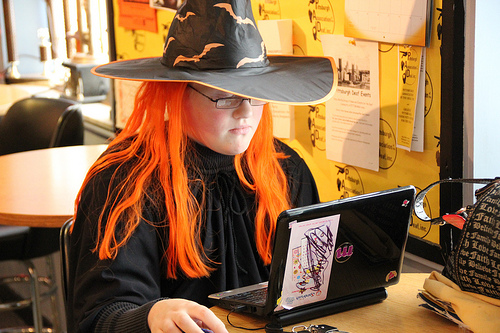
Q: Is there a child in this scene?
A: Yes, there is a child.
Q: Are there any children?
A: Yes, there is a child.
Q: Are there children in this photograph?
A: Yes, there is a child.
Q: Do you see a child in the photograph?
A: Yes, there is a child.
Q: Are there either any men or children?
A: Yes, there is a child.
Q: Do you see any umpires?
A: No, there are no umpires.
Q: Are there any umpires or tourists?
A: No, there are no umpires or tourists.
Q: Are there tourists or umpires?
A: No, there are no umpires or tourists.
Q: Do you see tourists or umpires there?
A: No, there are no umpires or tourists.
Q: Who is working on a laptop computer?
A: The child is working on a laptop computer.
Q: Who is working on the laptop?
A: The child is working on a laptop computer.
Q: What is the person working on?
A: The child is working on a laptop.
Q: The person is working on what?
A: The child is working on a laptop.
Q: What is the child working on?
A: The child is working on a laptop.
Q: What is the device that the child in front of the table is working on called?
A: The device is a laptop.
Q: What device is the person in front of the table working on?
A: The kid is working on a laptop.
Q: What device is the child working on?
A: The kid is working on a laptop.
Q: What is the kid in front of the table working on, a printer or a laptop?
A: The child is working on a laptop.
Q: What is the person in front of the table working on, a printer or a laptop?
A: The child is working on a laptop.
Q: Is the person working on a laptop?
A: Yes, the kid is working on a laptop.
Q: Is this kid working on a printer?
A: No, the kid is working on a laptop.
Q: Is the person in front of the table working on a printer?
A: No, the kid is working on a laptop.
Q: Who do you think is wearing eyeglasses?
A: The kid is wearing eyeglasses.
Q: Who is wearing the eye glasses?
A: The kid is wearing eyeglasses.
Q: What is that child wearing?
A: The child is wearing eye glasses.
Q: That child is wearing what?
A: The child is wearing eye glasses.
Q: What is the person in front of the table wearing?
A: The child is wearing eye glasses.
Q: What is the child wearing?
A: The child is wearing eye glasses.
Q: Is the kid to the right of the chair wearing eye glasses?
A: Yes, the child is wearing eye glasses.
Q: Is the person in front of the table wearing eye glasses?
A: Yes, the child is wearing eye glasses.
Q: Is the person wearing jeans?
A: No, the child is wearing eye glasses.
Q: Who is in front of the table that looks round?
A: The child is in front of the table.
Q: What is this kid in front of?
A: The kid is in front of the table.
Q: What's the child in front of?
A: The kid is in front of the table.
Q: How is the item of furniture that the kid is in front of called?
A: The piece of furniture is a table.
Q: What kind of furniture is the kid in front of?
A: The kid is in front of the table.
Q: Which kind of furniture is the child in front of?
A: The kid is in front of the table.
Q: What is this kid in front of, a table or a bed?
A: The kid is in front of a table.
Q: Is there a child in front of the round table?
A: Yes, there is a child in front of the table.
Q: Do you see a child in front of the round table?
A: Yes, there is a child in front of the table.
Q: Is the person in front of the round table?
A: Yes, the child is in front of the table.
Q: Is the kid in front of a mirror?
A: No, the kid is in front of the table.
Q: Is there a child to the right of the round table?
A: Yes, there is a child to the right of the table.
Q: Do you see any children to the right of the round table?
A: Yes, there is a child to the right of the table.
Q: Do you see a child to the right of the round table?
A: Yes, there is a child to the right of the table.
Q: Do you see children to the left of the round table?
A: No, the child is to the right of the table.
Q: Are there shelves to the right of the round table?
A: No, there is a child to the right of the table.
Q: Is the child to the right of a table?
A: Yes, the child is to the right of a table.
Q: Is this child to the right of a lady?
A: No, the child is to the right of a table.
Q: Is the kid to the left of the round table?
A: No, the kid is to the right of the table.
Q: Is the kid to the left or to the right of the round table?
A: The kid is to the right of the table.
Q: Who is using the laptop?
A: The child is using the laptop.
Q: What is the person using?
A: The kid is using a laptop computer.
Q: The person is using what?
A: The kid is using a laptop computer.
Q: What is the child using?
A: The kid is using a laptop computer.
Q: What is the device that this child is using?
A: The device is a laptop.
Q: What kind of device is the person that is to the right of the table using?
A: The child is using a laptop.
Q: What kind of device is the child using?
A: The child is using a laptop.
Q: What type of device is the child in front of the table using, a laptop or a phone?
A: The child is using a laptop.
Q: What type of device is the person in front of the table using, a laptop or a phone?
A: The child is using a laptop.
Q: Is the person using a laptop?
A: Yes, the kid is using a laptop.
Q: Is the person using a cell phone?
A: No, the kid is using a laptop.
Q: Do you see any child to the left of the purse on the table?
A: Yes, there is a child to the left of the purse.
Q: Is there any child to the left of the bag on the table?
A: Yes, there is a child to the left of the purse.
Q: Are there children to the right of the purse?
A: No, the child is to the left of the purse.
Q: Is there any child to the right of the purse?
A: No, the child is to the left of the purse.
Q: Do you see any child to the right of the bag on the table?
A: No, the child is to the left of the purse.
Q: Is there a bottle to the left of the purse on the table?
A: No, there is a child to the left of the purse.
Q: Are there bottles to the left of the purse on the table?
A: No, there is a child to the left of the purse.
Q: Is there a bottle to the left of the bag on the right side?
A: No, there is a child to the left of the purse.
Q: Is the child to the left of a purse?
A: Yes, the child is to the left of a purse.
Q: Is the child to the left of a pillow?
A: No, the child is to the left of a purse.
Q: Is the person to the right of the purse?
A: No, the child is to the left of the purse.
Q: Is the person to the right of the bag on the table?
A: No, the child is to the left of the purse.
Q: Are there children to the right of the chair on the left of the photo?
A: Yes, there is a child to the right of the chair.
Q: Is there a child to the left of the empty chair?
A: No, the child is to the right of the chair.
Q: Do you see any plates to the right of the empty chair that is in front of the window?
A: No, there is a child to the right of the chair.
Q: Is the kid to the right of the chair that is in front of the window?
A: Yes, the kid is to the right of the chair.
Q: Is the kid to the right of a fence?
A: No, the kid is to the right of the chair.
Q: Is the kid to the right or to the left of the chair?
A: The kid is to the right of the chair.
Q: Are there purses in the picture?
A: Yes, there is a purse.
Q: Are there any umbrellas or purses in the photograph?
A: Yes, there is a purse.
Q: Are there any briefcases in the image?
A: No, there are no briefcases.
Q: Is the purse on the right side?
A: Yes, the purse is on the right of the image.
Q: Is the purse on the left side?
A: No, the purse is on the right of the image.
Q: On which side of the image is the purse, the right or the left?
A: The purse is on the right of the image.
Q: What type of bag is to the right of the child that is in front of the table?
A: The bag is a purse.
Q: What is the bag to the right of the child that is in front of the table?
A: The bag is a purse.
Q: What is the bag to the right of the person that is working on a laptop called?
A: The bag is a purse.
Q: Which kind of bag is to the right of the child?
A: The bag is a purse.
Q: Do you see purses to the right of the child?
A: Yes, there is a purse to the right of the child.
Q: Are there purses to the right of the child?
A: Yes, there is a purse to the right of the child.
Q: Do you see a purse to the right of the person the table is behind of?
A: Yes, there is a purse to the right of the child.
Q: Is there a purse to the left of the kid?
A: No, the purse is to the right of the kid.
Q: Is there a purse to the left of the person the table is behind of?
A: No, the purse is to the right of the kid.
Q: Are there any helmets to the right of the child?
A: No, there is a purse to the right of the child.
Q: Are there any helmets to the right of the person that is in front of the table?
A: No, there is a purse to the right of the child.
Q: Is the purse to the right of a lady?
A: No, the purse is to the right of the kid.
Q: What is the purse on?
A: The purse is on the table.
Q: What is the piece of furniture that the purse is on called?
A: The piece of furniture is a table.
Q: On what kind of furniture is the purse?
A: The purse is on the table.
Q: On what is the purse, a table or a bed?
A: The purse is on a table.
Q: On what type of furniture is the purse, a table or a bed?
A: The purse is on a table.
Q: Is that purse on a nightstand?
A: No, the purse is on a table.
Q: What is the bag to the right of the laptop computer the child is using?
A: The bag is a purse.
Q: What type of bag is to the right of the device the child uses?
A: The bag is a purse.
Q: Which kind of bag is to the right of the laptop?
A: The bag is a purse.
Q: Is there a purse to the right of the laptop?
A: Yes, there is a purse to the right of the laptop.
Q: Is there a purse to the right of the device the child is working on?
A: Yes, there is a purse to the right of the laptop.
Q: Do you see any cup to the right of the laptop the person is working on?
A: No, there is a purse to the right of the laptop.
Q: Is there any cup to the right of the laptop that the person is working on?
A: No, there is a purse to the right of the laptop.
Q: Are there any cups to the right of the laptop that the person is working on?
A: No, there is a purse to the right of the laptop.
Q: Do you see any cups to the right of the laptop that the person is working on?
A: No, there is a purse to the right of the laptop.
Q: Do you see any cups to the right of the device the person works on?
A: No, there is a purse to the right of the laptop.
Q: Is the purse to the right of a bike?
A: No, the purse is to the right of a laptop.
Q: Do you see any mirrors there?
A: No, there are no mirrors.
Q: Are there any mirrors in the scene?
A: No, there are no mirrors.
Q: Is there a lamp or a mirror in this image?
A: No, there are no mirrors or lamps.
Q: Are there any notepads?
A: No, there are no notepads.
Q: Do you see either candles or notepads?
A: No, there are no notepads or candles.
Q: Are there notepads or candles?
A: No, there are no notepads or candles.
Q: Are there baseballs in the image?
A: No, there are no baseballs.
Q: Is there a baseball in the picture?
A: No, there are no baseballs.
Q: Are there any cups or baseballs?
A: No, there are no baseballs or cups.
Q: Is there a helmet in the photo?
A: No, there are no helmets.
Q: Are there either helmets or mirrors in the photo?
A: No, there are no helmets or mirrors.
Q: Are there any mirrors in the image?
A: No, there are no mirrors.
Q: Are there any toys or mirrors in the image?
A: No, there are no mirrors or toys.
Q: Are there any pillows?
A: No, there are no pillows.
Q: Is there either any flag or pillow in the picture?
A: No, there are no pillows or flags.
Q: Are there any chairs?
A: Yes, there is a chair.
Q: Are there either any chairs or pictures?
A: Yes, there is a chair.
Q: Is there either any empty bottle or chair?
A: Yes, there is an empty chair.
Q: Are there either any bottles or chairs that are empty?
A: Yes, the chair is empty.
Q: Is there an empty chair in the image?
A: Yes, there is an empty chair.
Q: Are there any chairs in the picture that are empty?
A: Yes, there is a chair that is empty.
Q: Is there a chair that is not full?
A: Yes, there is a empty chair.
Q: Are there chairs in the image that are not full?
A: Yes, there is a empty chair.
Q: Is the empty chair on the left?
A: Yes, the chair is on the left of the image.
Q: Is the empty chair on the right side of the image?
A: No, the chair is on the left of the image.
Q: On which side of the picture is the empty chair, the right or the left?
A: The chair is on the left of the image.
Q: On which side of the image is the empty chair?
A: The chair is on the left of the image.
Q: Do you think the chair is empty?
A: Yes, the chair is empty.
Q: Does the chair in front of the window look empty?
A: Yes, the chair is empty.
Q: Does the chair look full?
A: No, the chair is empty.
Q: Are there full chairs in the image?
A: No, there is a chair but it is empty.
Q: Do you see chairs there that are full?
A: No, there is a chair but it is empty.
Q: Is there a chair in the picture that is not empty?
A: No, there is a chair but it is empty.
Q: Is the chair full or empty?
A: The chair is empty.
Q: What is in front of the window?
A: The chair is in front of the window.